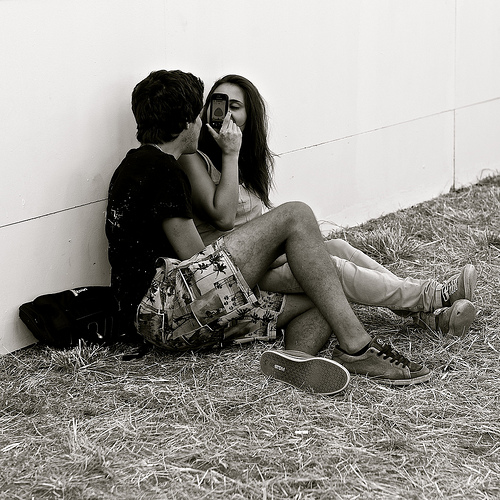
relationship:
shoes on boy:
[254, 338, 430, 408] [86, 58, 428, 420]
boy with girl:
[86, 58, 428, 420] [198, 71, 477, 342]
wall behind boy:
[2, 2, 500, 325] [86, 58, 428, 420]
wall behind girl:
[2, 2, 500, 325] [198, 71, 477, 342]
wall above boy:
[2, 2, 500, 325] [86, 58, 428, 420]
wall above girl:
[2, 2, 500, 325] [198, 71, 477, 342]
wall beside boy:
[2, 2, 500, 325] [86, 58, 428, 420]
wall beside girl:
[2, 2, 500, 325] [198, 71, 477, 342]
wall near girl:
[2, 2, 500, 325] [198, 71, 477, 342]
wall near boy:
[2, 2, 500, 325] [86, 58, 428, 420]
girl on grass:
[198, 71, 477, 342] [2, 173, 499, 494]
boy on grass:
[86, 58, 428, 420] [2, 173, 499, 494]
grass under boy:
[2, 173, 499, 494] [86, 58, 428, 420]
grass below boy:
[2, 173, 499, 494] [86, 58, 428, 420]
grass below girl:
[2, 173, 499, 494] [198, 71, 477, 342]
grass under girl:
[2, 173, 499, 494] [198, 71, 477, 342]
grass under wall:
[2, 173, 499, 494] [2, 2, 500, 325]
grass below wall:
[2, 173, 499, 494] [2, 2, 500, 325]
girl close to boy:
[198, 71, 477, 342] [86, 58, 428, 420]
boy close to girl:
[86, 58, 428, 420] [198, 71, 477, 342]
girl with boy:
[198, 71, 477, 342] [86, 58, 428, 420]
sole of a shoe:
[272, 371, 328, 401] [260, 344, 338, 448]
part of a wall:
[6, 224, 36, 350] [50, 99, 110, 176]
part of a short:
[190, 260, 264, 360] [142, 258, 268, 410]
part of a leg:
[328, 293, 346, 341] [239, 258, 385, 345]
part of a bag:
[10, 316, 59, 378] [44, 275, 104, 405]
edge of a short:
[227, 258, 265, 334] [210, 295, 240, 394]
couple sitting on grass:
[104, 64, 489, 399] [36, 355, 277, 485]